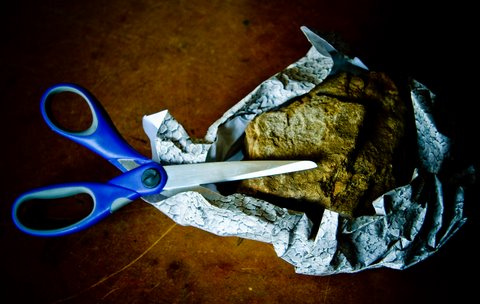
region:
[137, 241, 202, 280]
this is a table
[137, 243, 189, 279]
the table is wooden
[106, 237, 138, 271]
the table is brown in color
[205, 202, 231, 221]
this is a paper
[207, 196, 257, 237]
the paper is white in color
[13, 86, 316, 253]
a pair of scissors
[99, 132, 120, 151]
the handle is blue in color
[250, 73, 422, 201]
this is a rock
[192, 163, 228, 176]
the area is metallic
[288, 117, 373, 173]
the stone is big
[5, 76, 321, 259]
a blue pair of scissors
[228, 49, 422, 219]
a large brown rock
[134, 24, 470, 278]
a crumbled piece of paper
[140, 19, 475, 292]
crumbled paper is white with black lettering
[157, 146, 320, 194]
blade of scissors are gray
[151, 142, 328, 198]
blades of scissors are sharp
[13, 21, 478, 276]
a rock, a piece of paper and a pair of scissors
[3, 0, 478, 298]
a dark brown floor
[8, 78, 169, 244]
blue handles on a pair of scissors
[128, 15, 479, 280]
a rock sitting in a crumbled piece of paper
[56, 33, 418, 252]
scissors on a rock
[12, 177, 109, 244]
hole for the fingers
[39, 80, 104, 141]
hole at the top of the scissors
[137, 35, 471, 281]
food wrapped in paper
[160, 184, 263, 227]
blade partially hidden by paper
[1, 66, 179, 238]
handle of the scissors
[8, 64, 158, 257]
the handle is blue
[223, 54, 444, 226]
piece of food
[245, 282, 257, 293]
white speck on the ground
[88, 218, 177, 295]
white scratch on the ground